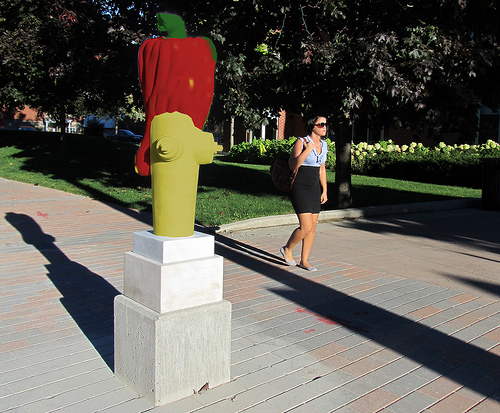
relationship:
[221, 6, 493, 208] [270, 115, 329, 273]
tree behind person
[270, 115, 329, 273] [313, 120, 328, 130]
person wearing sunglasses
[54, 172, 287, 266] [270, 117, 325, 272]
shadow of woman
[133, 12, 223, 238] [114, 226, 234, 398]
statue standing on pedestal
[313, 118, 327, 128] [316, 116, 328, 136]
sunglasses on face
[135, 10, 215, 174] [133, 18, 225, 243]
chili pepper on fire hydrant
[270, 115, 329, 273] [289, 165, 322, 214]
person wearing black skirt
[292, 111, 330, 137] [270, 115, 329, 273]
hair on person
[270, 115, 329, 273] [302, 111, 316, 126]
person has hair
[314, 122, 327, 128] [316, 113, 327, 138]
sunglasses on face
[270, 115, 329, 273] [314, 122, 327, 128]
person wearing sunglasses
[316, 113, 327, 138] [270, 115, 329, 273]
face on person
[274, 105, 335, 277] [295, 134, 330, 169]
person wearing shirt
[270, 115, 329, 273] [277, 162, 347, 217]
person wearing skirt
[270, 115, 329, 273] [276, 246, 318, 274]
person wearing flats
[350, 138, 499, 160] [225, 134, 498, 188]
flowers on plants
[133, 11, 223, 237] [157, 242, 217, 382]
fire hydrant on blocks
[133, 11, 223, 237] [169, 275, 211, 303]
fire hydrant on concrete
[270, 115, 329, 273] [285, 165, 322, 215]
person wearing skirt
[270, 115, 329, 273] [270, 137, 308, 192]
person carrying bag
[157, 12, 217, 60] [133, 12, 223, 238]
piece on statue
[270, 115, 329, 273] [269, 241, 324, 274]
person wearing flats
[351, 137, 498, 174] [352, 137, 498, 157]
wall of flowers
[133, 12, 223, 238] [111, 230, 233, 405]
statue on base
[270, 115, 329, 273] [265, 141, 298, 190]
person carrying bag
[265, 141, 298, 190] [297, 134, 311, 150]
bag on shoulder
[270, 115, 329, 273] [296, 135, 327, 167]
person wearing top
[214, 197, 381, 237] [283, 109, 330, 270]
curb behind woman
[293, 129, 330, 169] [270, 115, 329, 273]
shirt is on person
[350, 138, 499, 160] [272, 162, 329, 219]
flowers on pants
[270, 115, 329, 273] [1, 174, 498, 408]
person on pathway